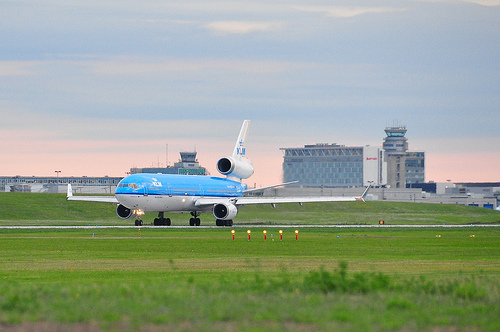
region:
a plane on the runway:
[36, 70, 371, 252]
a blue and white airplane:
[39, 82, 405, 269]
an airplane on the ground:
[37, 70, 325, 295]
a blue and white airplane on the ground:
[52, 113, 392, 253]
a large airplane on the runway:
[39, 105, 409, 232]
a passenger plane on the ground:
[53, 120, 399, 271]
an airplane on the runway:
[48, 80, 381, 232]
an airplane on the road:
[33, 43, 397, 270]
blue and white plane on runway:
[63, 117, 368, 229]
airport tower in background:
[381, 122, 411, 187]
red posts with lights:
[228, 225, 300, 242]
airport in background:
[1, 120, 497, 207]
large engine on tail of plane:
[215, 155, 253, 178]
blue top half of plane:
[113, 173, 244, 195]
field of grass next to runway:
[0, 225, 498, 330]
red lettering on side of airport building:
[366, 154, 379, 161]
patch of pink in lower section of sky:
[1, 142, 499, 189]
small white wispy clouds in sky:
[187, 2, 404, 34]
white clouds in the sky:
[108, 46, 201, 103]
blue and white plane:
[50, 122, 321, 263]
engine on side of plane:
[205, 191, 240, 223]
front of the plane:
[85, 165, 162, 216]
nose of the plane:
[106, 167, 147, 212]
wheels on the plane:
[145, 210, 215, 240]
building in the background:
[290, 132, 362, 189]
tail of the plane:
[205, 115, 265, 165]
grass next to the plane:
[30, 241, 70, 262]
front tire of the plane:
[122, 211, 147, 236]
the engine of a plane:
[216, 152, 261, 181]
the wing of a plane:
[188, 180, 383, 216]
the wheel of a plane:
[185, 210, 207, 230]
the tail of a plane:
[211, 113, 261, 181]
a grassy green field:
[4, 225, 498, 330]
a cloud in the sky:
[200, 10, 312, 42]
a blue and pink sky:
[0, 0, 498, 176]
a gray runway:
[0, 219, 499, 234]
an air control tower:
[370, 120, 415, 189]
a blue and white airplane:
[66, 116, 371, 227]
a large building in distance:
[279, 141, 380, 186]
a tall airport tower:
[381, 124, 410, 186]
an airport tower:
[174, 149, 199, 168]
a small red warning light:
[229, 227, 238, 240]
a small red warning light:
[246, 227, 253, 239]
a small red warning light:
[259, 226, 269, 241]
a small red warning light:
[277, 227, 284, 242]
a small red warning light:
[293, 230, 301, 243]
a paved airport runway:
[2, 219, 499, 230]